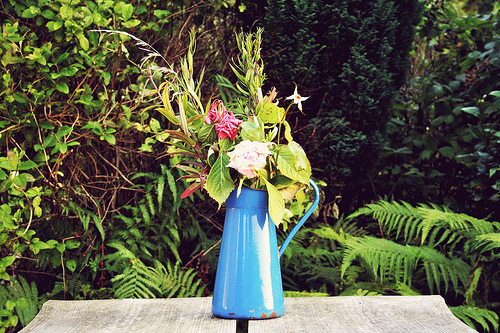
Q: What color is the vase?
A: Blue.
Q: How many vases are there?
A: One.